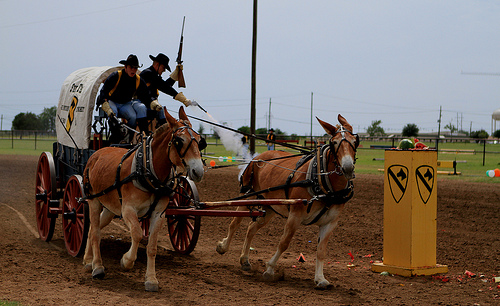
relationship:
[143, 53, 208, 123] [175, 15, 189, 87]
man shooting gun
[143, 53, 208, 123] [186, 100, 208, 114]
man shooting gun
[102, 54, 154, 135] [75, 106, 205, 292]
man steering horse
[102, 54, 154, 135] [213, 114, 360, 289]
man steering horse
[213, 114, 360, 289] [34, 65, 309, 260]
horse pulling covered wagon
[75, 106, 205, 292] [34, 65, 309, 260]
horse pulling covered wagon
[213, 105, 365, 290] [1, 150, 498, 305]
mule on track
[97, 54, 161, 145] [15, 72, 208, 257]
man on wagon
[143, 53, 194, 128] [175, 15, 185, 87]
man holding gun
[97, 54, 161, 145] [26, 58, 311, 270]
man driving wagon